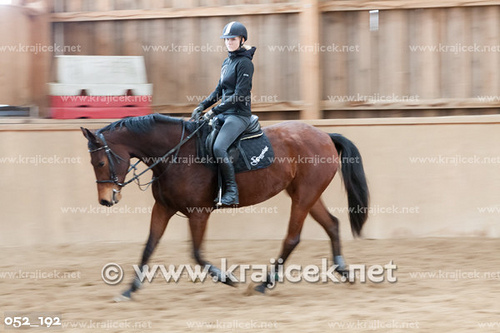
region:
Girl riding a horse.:
[76, 14, 394, 296]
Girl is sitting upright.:
[76, 16, 396, 303]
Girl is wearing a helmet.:
[78, 12, 383, 292]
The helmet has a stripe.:
[68, 17, 398, 313]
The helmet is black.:
[72, 12, 389, 314]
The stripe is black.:
[48, 10, 385, 309]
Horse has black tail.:
[69, 91, 386, 304]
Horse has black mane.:
[68, 90, 390, 302]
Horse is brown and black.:
[71, 90, 396, 304]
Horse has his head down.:
[68, 97, 393, 307]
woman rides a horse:
[42, 18, 466, 322]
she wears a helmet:
[204, 14, 276, 110]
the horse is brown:
[70, 88, 402, 273]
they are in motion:
[62, 13, 437, 295]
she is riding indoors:
[57, 23, 447, 288]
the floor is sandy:
[390, 248, 474, 304]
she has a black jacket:
[36, 26, 498, 256]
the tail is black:
[311, 125, 399, 251]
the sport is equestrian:
[61, 21, 433, 275]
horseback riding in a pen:
[62, 27, 435, 281]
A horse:
[60, 101, 441, 316]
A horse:
[210, 124, 307, 210]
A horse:
[174, 166, 376, 288]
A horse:
[154, 136, 254, 223]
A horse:
[173, 136, 323, 243]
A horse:
[94, 134, 251, 156]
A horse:
[139, 91, 331, 293]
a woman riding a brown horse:
[84, 20, 371, 301]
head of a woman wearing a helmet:
[221, 21, 249, 52]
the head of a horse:
[76, 118, 136, 205]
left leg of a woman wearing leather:
[199, 111, 271, 207]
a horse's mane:
[98, 111, 183, 133]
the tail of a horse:
[326, 128, 368, 237]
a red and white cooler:
[44, 56, 152, 118]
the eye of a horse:
[95, 156, 107, 169]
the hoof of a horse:
[113, 290, 130, 301]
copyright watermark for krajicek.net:
[96, 259, 401, 289]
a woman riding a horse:
[68, 11, 383, 285]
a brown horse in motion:
[91, 114, 353, 281]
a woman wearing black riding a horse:
[210, 21, 275, 178]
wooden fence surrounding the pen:
[262, 0, 472, 118]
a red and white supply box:
[36, 41, 164, 116]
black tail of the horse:
[321, 128, 384, 233]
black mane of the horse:
[93, 112, 183, 134]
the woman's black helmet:
[221, 16, 256, 47]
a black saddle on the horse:
[226, 111, 280, 178]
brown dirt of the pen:
[20, 280, 465, 322]